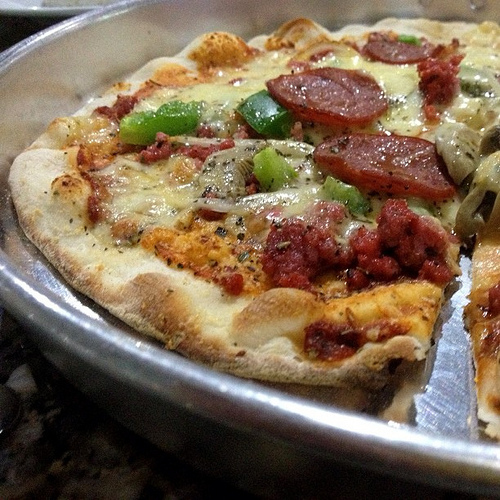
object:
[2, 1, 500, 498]
pan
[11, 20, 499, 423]
pizza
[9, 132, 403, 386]
crust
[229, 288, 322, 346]
bubble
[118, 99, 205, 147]
peppers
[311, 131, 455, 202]
sausage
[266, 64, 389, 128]
pepperoni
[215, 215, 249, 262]
seasoning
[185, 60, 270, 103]
cheese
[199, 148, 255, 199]
mushrooms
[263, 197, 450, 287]
sauce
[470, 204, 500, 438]
slice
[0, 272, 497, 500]
counter